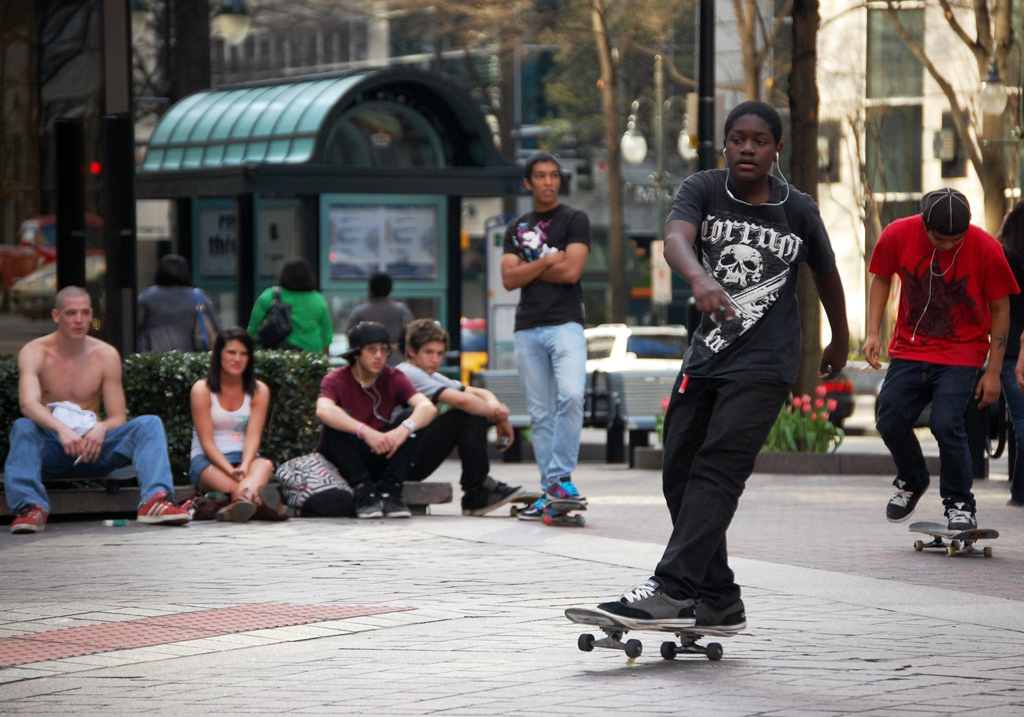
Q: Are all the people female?
A: No, they are both male and female.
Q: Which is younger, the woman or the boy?
A: The boy is younger than the woman.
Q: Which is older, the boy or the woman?
A: The woman is older than the boy.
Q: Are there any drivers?
A: No, there are no drivers.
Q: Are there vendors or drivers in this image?
A: No, there are no drivers or vendors.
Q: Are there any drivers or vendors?
A: No, there are no drivers or vendors.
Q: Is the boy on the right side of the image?
A: Yes, the boy is on the right of the image.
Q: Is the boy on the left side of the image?
A: No, the boy is on the right of the image.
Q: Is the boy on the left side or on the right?
A: The boy is on the right of the image.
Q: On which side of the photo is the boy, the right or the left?
A: The boy is on the right of the image.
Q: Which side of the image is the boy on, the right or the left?
A: The boy is on the right of the image.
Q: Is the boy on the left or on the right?
A: The boy is on the right of the image.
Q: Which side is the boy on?
A: The boy is on the right of the image.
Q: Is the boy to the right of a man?
A: Yes, the boy is to the right of a man.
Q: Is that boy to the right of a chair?
A: No, the boy is to the right of a man.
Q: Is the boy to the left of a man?
A: No, the boy is to the right of a man.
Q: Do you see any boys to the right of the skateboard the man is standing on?
A: Yes, there is a boy to the right of the skateboard.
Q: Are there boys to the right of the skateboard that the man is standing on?
A: Yes, there is a boy to the right of the skateboard.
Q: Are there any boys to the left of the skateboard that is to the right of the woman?
A: No, the boy is to the right of the skateboard.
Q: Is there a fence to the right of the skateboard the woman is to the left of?
A: No, there is a boy to the right of the skateboard.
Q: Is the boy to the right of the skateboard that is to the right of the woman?
A: Yes, the boy is to the right of the skateboard.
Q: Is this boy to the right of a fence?
A: No, the boy is to the right of the skateboard.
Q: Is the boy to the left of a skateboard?
A: No, the boy is to the right of a skateboard.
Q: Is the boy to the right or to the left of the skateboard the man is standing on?
A: The boy is to the right of the skateboard.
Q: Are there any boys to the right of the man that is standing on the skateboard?
A: Yes, there is a boy to the right of the man.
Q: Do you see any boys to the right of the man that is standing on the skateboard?
A: Yes, there is a boy to the right of the man.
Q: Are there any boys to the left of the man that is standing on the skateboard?
A: No, the boy is to the right of the man.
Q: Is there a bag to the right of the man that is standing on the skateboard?
A: No, there is a boy to the right of the man.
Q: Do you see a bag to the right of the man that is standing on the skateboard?
A: No, there is a boy to the right of the man.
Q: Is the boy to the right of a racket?
A: No, the boy is to the right of a man.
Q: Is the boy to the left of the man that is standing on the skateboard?
A: No, the boy is to the right of the man.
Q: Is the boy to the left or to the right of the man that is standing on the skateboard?
A: The boy is to the right of the man.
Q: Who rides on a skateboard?
A: The boy rides on a skateboard.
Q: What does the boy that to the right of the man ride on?
A: The boy rides on a skateboard.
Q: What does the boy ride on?
A: The boy rides on a skateboard.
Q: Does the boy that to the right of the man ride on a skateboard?
A: Yes, the boy rides on a skateboard.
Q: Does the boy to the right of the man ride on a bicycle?
A: No, the boy rides on a skateboard.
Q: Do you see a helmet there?
A: No, there are no helmets.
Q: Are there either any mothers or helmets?
A: No, there are no helmets or mothers.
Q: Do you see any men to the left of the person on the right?
A: Yes, there is a man to the left of the boy.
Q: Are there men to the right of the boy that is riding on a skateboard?
A: No, the man is to the left of the boy.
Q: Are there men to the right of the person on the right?
A: No, the man is to the left of the boy.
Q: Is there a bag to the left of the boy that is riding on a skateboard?
A: No, there is a man to the left of the boy.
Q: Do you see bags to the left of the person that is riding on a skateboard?
A: No, there is a man to the left of the boy.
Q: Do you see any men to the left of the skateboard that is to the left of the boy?
A: Yes, there is a man to the left of the skateboard.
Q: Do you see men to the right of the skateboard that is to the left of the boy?
A: No, the man is to the left of the skateboard.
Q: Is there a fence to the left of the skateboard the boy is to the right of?
A: No, there is a man to the left of the skateboard.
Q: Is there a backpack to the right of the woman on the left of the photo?
A: No, there is a man to the right of the woman.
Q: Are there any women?
A: Yes, there is a woman.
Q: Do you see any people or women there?
A: Yes, there is a woman.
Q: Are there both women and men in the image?
A: Yes, there are both a woman and a man.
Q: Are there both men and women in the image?
A: Yes, there are both a woman and a man.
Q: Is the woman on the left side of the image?
A: Yes, the woman is on the left of the image.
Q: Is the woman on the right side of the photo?
A: No, the woman is on the left of the image.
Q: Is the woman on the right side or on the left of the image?
A: The woman is on the left of the image.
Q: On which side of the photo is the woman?
A: The woman is on the left of the image.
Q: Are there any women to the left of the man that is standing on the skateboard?
A: Yes, there is a woman to the left of the man.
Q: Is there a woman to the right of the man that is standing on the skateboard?
A: No, the woman is to the left of the man.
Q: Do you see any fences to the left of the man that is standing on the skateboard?
A: No, there is a woman to the left of the man.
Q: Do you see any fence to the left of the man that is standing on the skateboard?
A: No, there is a woman to the left of the man.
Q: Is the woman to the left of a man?
A: Yes, the woman is to the left of a man.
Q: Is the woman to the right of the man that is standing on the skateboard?
A: No, the woman is to the left of the man.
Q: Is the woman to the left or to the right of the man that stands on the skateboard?
A: The woman is to the left of the man.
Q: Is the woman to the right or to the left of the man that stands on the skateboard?
A: The woman is to the left of the man.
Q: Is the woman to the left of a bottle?
A: No, the woman is to the left of a man.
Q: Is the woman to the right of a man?
A: No, the woman is to the left of a man.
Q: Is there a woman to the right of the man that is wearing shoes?
A: Yes, there is a woman to the right of the man.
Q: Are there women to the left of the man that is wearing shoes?
A: No, the woman is to the right of the man.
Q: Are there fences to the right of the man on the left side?
A: No, there is a woman to the right of the man.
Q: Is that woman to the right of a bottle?
A: No, the woman is to the right of a man.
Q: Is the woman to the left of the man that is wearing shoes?
A: No, the woman is to the right of the man.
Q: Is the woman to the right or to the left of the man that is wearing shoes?
A: The woman is to the right of the man.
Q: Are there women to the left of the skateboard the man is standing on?
A: Yes, there is a woman to the left of the skateboard.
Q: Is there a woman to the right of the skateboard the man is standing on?
A: No, the woman is to the left of the skateboard.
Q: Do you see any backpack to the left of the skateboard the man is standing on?
A: No, there is a woman to the left of the skateboard.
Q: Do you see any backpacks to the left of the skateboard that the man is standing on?
A: No, there is a woman to the left of the skateboard.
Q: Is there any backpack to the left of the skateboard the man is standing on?
A: No, there is a woman to the left of the skateboard.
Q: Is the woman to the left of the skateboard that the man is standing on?
A: Yes, the woman is to the left of the skateboard.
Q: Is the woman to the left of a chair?
A: No, the woman is to the left of the skateboard.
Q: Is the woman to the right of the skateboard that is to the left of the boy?
A: No, the woman is to the left of the skateboard.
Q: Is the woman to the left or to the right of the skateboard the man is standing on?
A: The woman is to the left of the skateboard.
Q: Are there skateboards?
A: Yes, there is a skateboard.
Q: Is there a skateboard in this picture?
A: Yes, there is a skateboard.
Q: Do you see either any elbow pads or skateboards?
A: Yes, there is a skateboard.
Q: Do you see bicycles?
A: No, there are no bicycles.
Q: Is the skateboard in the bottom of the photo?
A: Yes, the skateboard is in the bottom of the image.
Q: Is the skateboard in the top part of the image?
A: No, the skateboard is in the bottom of the image.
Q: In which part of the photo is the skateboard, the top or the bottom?
A: The skateboard is in the bottom of the image.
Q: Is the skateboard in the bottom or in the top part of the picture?
A: The skateboard is in the bottom of the image.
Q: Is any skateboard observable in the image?
A: Yes, there is a skateboard.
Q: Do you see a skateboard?
A: Yes, there is a skateboard.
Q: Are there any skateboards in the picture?
A: Yes, there is a skateboard.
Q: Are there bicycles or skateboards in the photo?
A: Yes, there is a skateboard.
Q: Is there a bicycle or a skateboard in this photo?
A: Yes, there is a skateboard.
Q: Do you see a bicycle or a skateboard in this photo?
A: Yes, there is a skateboard.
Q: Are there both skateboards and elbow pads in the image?
A: No, there is a skateboard but no elbow pads.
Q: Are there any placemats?
A: No, there are no placemats.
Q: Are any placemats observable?
A: No, there are no placemats.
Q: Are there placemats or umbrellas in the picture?
A: No, there are no placemats or umbrellas.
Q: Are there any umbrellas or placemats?
A: No, there are no placemats or umbrellas.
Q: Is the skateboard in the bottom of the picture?
A: Yes, the skateboard is in the bottom of the image.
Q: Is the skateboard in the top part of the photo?
A: No, the skateboard is in the bottom of the image.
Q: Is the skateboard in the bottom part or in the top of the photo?
A: The skateboard is in the bottom of the image.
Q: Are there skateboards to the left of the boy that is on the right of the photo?
A: Yes, there is a skateboard to the left of the boy.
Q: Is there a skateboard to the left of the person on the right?
A: Yes, there is a skateboard to the left of the boy.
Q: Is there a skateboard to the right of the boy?
A: No, the skateboard is to the left of the boy.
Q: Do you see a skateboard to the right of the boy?
A: No, the skateboard is to the left of the boy.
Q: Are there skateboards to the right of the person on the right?
A: No, the skateboard is to the left of the boy.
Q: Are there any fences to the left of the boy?
A: No, there is a skateboard to the left of the boy.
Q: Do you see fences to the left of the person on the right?
A: No, there is a skateboard to the left of the boy.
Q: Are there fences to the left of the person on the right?
A: No, there is a skateboard to the left of the boy.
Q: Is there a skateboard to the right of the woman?
A: Yes, there is a skateboard to the right of the woman.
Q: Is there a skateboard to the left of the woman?
A: No, the skateboard is to the right of the woman.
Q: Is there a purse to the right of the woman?
A: No, there is a skateboard to the right of the woman.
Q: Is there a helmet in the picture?
A: No, there are no helmets.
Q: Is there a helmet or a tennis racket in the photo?
A: No, there are no helmets or rackets.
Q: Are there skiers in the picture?
A: No, there are no skiers.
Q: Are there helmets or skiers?
A: No, there are no skiers or helmets.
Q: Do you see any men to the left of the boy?
A: Yes, there is a man to the left of the boy.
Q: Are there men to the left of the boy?
A: Yes, there is a man to the left of the boy.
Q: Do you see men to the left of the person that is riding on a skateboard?
A: Yes, there is a man to the left of the boy.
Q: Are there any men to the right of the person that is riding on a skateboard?
A: No, the man is to the left of the boy.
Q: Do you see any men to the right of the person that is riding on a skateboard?
A: No, the man is to the left of the boy.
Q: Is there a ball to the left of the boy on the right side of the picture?
A: No, there is a man to the left of the boy.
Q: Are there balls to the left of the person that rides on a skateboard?
A: No, there is a man to the left of the boy.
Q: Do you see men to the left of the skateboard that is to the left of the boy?
A: Yes, there is a man to the left of the skateboard.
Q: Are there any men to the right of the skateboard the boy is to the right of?
A: No, the man is to the left of the skateboard.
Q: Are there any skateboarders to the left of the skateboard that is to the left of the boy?
A: No, there is a man to the left of the skateboard.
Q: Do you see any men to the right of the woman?
A: Yes, there is a man to the right of the woman.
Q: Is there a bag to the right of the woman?
A: No, there is a man to the right of the woman.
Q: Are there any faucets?
A: No, there are no faucets.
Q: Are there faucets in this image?
A: No, there are no faucets.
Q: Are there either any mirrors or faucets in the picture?
A: No, there are no faucets or mirrors.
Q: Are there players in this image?
A: No, there are no players.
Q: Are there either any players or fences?
A: No, there are no players or fences.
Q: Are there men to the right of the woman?
A: Yes, there is a man to the right of the woman.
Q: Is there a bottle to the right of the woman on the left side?
A: No, there is a man to the right of the woman.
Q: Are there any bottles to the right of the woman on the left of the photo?
A: No, there is a man to the right of the woman.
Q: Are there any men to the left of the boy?
A: Yes, there is a man to the left of the boy.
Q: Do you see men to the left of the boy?
A: Yes, there is a man to the left of the boy.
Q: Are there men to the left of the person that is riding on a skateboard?
A: Yes, there is a man to the left of the boy.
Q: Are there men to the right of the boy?
A: No, the man is to the left of the boy.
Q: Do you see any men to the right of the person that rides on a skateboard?
A: No, the man is to the left of the boy.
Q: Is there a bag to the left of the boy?
A: No, there is a man to the left of the boy.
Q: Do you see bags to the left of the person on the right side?
A: No, there is a man to the left of the boy.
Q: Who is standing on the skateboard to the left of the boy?
A: The man is standing on the skateboard.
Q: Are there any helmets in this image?
A: No, there are no helmets.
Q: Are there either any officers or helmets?
A: No, there are no helmets or officers.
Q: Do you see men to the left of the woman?
A: Yes, there is a man to the left of the woman.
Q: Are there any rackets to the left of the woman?
A: No, there is a man to the left of the woman.